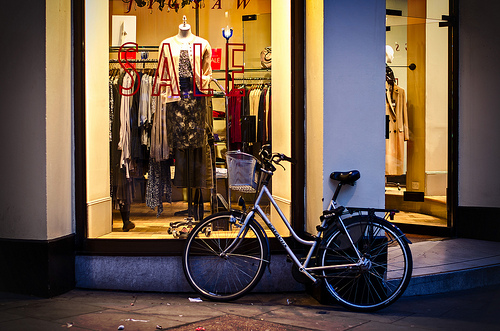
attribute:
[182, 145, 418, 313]
bicycle — leaning, parked, silver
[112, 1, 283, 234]
window — display, large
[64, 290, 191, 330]
sidewalk — concrete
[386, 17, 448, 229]
door — glass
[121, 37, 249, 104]
sale — word, sign, decal, red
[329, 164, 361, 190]
seat — black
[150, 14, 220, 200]
mannequn — headless, displayed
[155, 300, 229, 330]
pavement — littered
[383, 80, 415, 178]
coat — tan